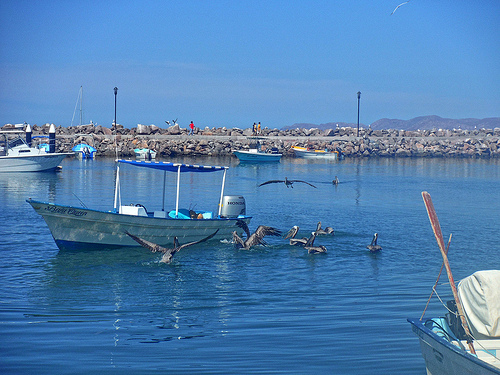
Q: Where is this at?
A: Pier.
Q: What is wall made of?
A: Rock.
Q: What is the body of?
A: Water.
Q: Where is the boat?
A: In water.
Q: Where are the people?
A: Shoreline.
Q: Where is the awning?
A: On boat.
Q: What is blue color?
A: Canopy.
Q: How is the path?
A: Rocky.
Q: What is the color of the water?
A: Blue.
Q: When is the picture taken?
A: Daytime.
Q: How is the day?
A: Sunny.